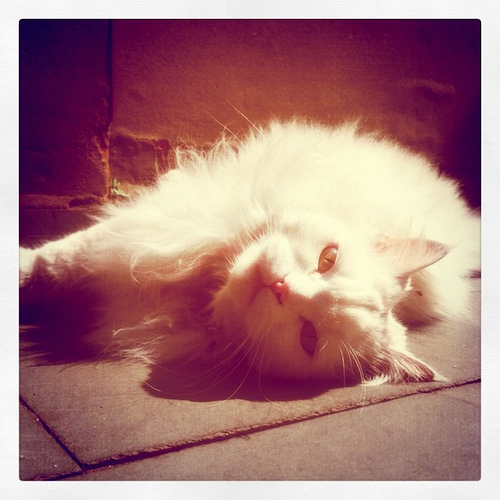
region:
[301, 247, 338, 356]
The eyes of the cat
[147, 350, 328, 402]
A shadow on the ground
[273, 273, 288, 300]
The nose of the cat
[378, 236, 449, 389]
The ears of thecat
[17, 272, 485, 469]
A mat below the cat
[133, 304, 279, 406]
The whiskers of the cat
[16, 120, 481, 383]
A white cat on the ground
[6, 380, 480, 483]
The ground below the mat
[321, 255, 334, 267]
The pupil of the eye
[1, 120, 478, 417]
The cat has white fur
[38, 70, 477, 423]
white fluffy cat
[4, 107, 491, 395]
white cat laying on its side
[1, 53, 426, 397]
white cat laying on rug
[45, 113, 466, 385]
white cat laying looking at camera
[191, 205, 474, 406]
white fluffy cats face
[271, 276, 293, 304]
white cat has pink nose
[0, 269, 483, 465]
rug white cat is laing on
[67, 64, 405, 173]
cats hair sticking out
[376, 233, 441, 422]
cats ears perked up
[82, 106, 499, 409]
cat laying but not sleeping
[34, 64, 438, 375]
a fluffy white cat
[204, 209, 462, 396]
the cat's head is turned sideways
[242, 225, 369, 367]
the cat's eyes are yellow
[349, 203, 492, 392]
the cat has pointy ears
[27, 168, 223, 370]
the cat's legs are white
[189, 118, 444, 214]
the cat has fluffy white fur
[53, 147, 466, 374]
the cat is lying down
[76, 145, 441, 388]
this cat is posing for the picture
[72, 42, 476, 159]
a brown background behind the cat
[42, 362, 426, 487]
the cat is lying on tile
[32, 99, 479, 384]
all white cat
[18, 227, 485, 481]
floor cat is laying on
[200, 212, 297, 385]
whiskers of white cat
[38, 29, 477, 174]
wall behind white cat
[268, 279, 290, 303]
pink nose of white cat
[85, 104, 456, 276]
fuzzy fur of the white cat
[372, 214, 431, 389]
white hair in the ears of cat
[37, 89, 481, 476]
cat laying on gray pavement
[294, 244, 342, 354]
eyes of cat with black slit irises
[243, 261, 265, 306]
mouth of white cat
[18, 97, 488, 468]
a white cat over a rug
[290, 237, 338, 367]
eyes of cat are big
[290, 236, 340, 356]
eyes of cat are brown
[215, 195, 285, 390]
white whiskers of cat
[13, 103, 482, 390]
cat has white fur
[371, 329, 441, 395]
right ear of cat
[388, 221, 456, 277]
left ear of cat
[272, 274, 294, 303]
nose of cat is pink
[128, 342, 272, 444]
a shadow on a rug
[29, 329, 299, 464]
a brown rug on the floor